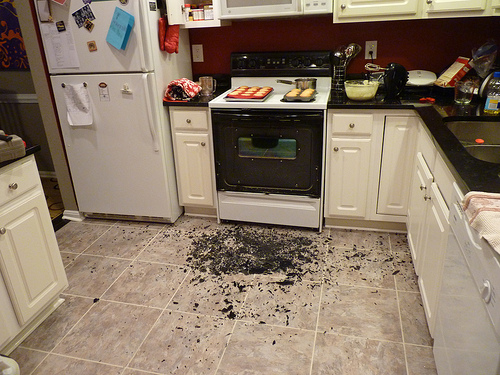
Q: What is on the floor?
A: Black stuff.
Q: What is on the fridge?
A: Many things.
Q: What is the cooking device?
A: Black and white oven.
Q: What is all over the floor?
A: Broken glass.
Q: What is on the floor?
A: Dirt.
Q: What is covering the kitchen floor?
A: Tiles.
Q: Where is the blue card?
A: On the fridge.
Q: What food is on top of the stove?
A: Muffins or cupcakes.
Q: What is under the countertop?
A: White cabinets.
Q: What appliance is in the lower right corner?
A: Dishwasher.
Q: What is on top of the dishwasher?
A: Towel.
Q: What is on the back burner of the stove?
A: Silver pot.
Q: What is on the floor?
A: Dirt.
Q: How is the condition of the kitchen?
A: Dirty.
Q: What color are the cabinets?
A: White.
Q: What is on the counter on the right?
A: Towel.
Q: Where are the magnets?
A: Fridge.